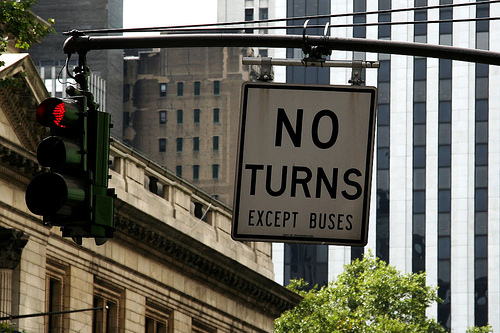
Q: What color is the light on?
A: Red.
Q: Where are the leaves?
A: On the tree.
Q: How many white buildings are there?
A: 1.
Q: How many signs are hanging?
A: 1.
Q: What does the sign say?
A: No turns except buses.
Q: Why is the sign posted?
A: To indicate no turns are allowed.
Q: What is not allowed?
A: Turns.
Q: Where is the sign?
A: Next to the traffic light.